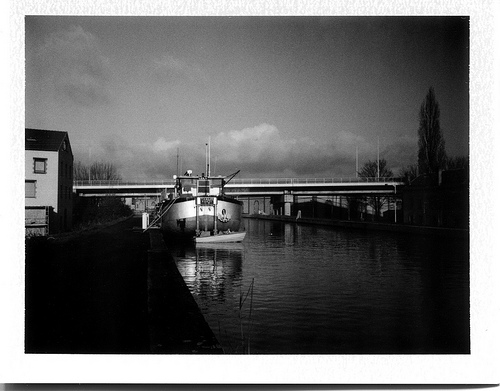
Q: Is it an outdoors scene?
A: Yes, it is outdoors.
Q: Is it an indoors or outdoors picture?
A: It is outdoors.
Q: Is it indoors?
A: No, it is outdoors.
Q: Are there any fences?
A: No, there are no fences.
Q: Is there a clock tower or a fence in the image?
A: No, there are no fences or clock towers.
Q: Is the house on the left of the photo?
A: Yes, the house is on the left of the image.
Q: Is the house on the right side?
A: No, the house is on the left of the image.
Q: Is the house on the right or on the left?
A: The house is on the left of the image.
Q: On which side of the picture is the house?
A: The house is on the left of the image.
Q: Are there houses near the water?
A: Yes, there is a house near the water.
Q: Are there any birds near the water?
A: No, there is a house near the water.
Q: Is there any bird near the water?
A: No, there is a house near the water.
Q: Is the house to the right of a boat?
A: No, the house is to the left of a boat.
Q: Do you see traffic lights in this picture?
A: No, there are no traffic lights.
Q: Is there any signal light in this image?
A: No, there are no traffic lights.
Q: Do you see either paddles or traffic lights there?
A: No, there are no traffic lights or paddles.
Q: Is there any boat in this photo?
A: Yes, there is a boat.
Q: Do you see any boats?
A: Yes, there is a boat.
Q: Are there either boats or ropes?
A: Yes, there is a boat.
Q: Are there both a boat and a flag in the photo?
A: No, there is a boat but no flags.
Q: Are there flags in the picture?
A: No, there are no flags.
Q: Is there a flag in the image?
A: No, there are no flags.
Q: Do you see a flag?
A: No, there are no flags.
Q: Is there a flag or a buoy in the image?
A: No, there are no flags or buoys.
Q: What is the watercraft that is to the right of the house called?
A: The watercraft is a boat.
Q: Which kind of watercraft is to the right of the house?
A: The watercraft is a boat.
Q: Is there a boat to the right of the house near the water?
A: Yes, there is a boat to the right of the house.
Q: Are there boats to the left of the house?
A: No, the boat is to the right of the house.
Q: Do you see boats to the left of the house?
A: No, the boat is to the right of the house.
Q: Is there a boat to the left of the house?
A: No, the boat is to the right of the house.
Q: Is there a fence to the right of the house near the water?
A: No, there is a boat to the right of the house.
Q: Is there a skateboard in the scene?
A: No, there are no skateboards.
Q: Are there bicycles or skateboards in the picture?
A: No, there are no skateboards or bicycles.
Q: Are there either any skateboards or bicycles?
A: No, there are no skateboards or bicycles.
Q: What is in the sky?
A: The clouds are in the sky.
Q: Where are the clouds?
A: The clouds are in the sky.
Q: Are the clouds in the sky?
A: Yes, the clouds are in the sky.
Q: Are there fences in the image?
A: No, there are no fences.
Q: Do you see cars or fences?
A: No, there are no fences or cars.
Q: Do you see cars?
A: No, there are no cars.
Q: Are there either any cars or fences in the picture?
A: No, there are no cars or fences.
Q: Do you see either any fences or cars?
A: No, there are no cars or fences.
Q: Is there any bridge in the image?
A: Yes, there is a bridge.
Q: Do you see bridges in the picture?
A: Yes, there is a bridge.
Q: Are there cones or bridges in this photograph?
A: Yes, there is a bridge.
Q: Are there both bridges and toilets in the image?
A: No, there is a bridge but no toilets.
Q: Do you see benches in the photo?
A: No, there are no benches.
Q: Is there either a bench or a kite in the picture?
A: No, there are no benches or kites.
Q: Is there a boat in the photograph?
A: Yes, there is a boat.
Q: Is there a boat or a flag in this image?
A: Yes, there is a boat.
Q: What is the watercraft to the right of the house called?
A: The watercraft is a boat.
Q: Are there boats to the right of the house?
A: Yes, there is a boat to the right of the house.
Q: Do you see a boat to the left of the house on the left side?
A: No, the boat is to the right of the house.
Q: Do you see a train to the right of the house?
A: No, there is a boat to the right of the house.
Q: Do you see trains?
A: No, there are no trains.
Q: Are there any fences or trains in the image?
A: No, there are no trains or fences.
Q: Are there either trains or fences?
A: No, there are no trains or fences.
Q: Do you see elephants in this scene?
A: No, there are no elephants.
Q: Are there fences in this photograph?
A: No, there are no fences.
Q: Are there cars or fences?
A: No, there are no fences or cars.